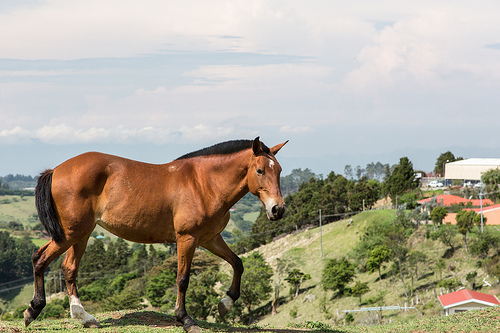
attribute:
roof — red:
[436, 277, 498, 319]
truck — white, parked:
[423, 177, 443, 189]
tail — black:
[31, 165, 68, 251]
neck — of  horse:
[210, 144, 250, 211]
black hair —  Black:
[172, 137, 277, 159]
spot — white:
[266, 157, 276, 172]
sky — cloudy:
[156, 0, 341, 58]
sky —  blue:
[0, 1, 498, 181]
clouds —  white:
[2, 0, 499, 182]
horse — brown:
[34, 118, 338, 331]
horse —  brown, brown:
[20, 138, 292, 331]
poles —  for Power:
[18, 266, 92, 302]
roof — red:
[438, 284, 499, 310]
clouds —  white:
[370, 16, 481, 74]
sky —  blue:
[3, 3, 497, 133]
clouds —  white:
[360, 20, 450, 81]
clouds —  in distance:
[2, 123, 253, 142]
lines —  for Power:
[1, 278, 35, 291]